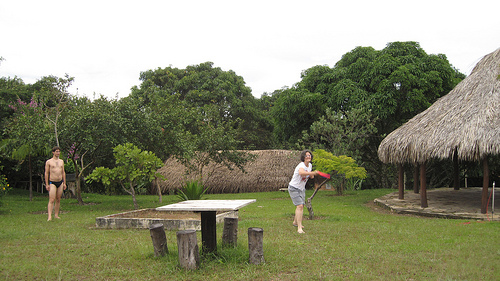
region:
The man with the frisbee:
[281, 141, 335, 238]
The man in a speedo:
[41, 141, 74, 226]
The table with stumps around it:
[138, 183, 272, 273]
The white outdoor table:
[156, 193, 256, 254]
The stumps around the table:
[145, 211, 266, 273]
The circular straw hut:
[363, 36, 499, 220]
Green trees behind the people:
[0, 32, 492, 188]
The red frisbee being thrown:
[311, 163, 334, 179]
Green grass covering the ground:
[0, 185, 496, 276]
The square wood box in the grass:
[96, 202, 238, 236]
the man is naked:
[26, 106, 123, 231]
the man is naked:
[24, 83, 90, 180]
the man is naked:
[51, 160, 148, 278]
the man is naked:
[21, 100, 171, 274]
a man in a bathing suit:
[38, 133, 74, 231]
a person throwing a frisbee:
[288, 147, 336, 237]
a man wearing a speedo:
[34, 138, 80, 228]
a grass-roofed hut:
[373, 45, 493, 227]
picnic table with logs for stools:
[151, 186, 268, 272]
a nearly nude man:
[34, 141, 84, 236]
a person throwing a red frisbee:
[281, 141, 343, 237]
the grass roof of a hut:
[149, 140, 289, 198]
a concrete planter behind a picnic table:
[111, 187, 243, 245]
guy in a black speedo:
[34, 141, 79, 234]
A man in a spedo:
[27, 139, 94, 246]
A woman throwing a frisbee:
[274, 139, 347, 227]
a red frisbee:
[314, 163, 339, 189]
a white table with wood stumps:
[141, 186, 283, 277]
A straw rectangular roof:
[146, 129, 315, 206]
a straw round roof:
[374, 21, 498, 163]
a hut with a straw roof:
[378, 41, 498, 229]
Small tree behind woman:
[286, 151, 381, 232]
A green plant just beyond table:
[168, 180, 217, 212]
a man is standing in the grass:
[30, 138, 80, 225]